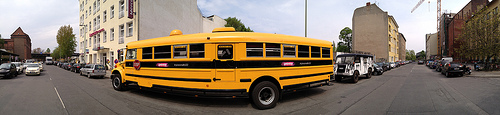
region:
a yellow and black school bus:
[79, 25, 376, 104]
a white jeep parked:
[311, 41, 384, 109]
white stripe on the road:
[41, 68, 76, 113]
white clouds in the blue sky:
[252, 5, 337, 26]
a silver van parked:
[65, 59, 109, 79]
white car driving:
[21, 51, 41, 81]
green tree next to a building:
[52, 16, 88, 65]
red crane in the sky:
[405, 0, 447, 61]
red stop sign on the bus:
[129, 51, 154, 88]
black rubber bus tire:
[237, 62, 287, 113]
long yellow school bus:
[111, 25, 333, 107]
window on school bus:
[216, 43, 231, 58]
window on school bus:
[323, 46, 330, 55]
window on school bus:
[311, 46, 320, 58]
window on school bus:
[297, 44, 307, 58]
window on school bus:
[264, 42, 280, 55]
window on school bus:
[245, 42, 262, 53]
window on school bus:
[187, 45, 205, 57]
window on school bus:
[171, 42, 187, 55]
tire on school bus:
[249, 80, 277, 107]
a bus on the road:
[94, 4, 347, 111]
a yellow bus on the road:
[103, 17, 355, 114]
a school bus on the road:
[107, 5, 351, 113]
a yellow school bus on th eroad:
[96, 10, 364, 113]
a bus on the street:
[111, 20, 361, 113]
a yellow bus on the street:
[115, 24, 325, 112]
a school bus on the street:
[90, 9, 400, 107]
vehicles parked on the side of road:
[330, 15, 494, 109]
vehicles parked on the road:
[315, 27, 497, 113]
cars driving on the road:
[4, 41, 71, 111]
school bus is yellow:
[111, 26, 336, 111]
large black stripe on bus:
[123, 59, 336, 69]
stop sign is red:
[132, 58, 140, 68]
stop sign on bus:
[131, 58, 140, 68]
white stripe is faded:
[45, 71, 65, 114]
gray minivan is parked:
[80, 62, 106, 78]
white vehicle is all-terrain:
[331, 52, 373, 83]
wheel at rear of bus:
[250, 79, 280, 109]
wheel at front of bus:
[110, 69, 120, 89]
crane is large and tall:
[407, 1, 442, 51]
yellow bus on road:
[87, 26, 340, 88]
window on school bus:
[139, 45, 155, 63]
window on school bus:
[122, 50, 138, 64]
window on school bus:
[155, 43, 172, 58]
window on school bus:
[284, 41, 295, 55]